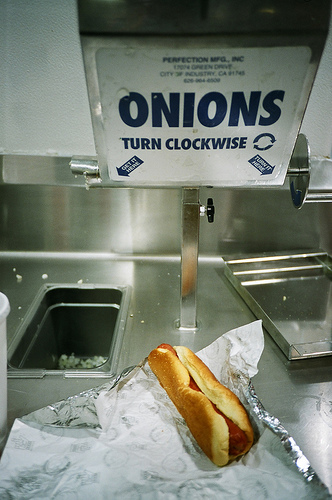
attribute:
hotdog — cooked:
[147, 335, 262, 467]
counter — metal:
[5, 333, 331, 497]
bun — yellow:
[139, 344, 194, 396]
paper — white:
[21, 374, 187, 494]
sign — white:
[82, 21, 306, 194]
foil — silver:
[255, 398, 321, 482]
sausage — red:
[214, 403, 255, 465]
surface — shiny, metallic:
[9, 234, 151, 281]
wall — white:
[6, 2, 113, 152]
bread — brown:
[160, 361, 201, 419]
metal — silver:
[75, 224, 175, 291]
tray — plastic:
[231, 249, 328, 362]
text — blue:
[106, 45, 284, 183]